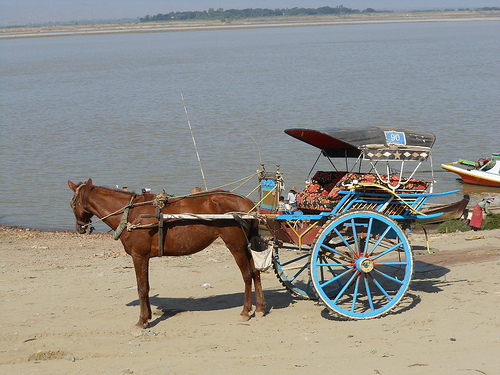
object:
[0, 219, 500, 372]
road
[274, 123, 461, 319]
cart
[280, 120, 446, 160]
cart cover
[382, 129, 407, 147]
number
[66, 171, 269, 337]
horse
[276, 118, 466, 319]
buggy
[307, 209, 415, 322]
wheel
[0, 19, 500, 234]
water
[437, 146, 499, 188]
boat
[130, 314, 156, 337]
hooves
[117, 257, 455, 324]
shadow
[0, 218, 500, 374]
ground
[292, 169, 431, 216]
seat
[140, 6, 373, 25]
trees